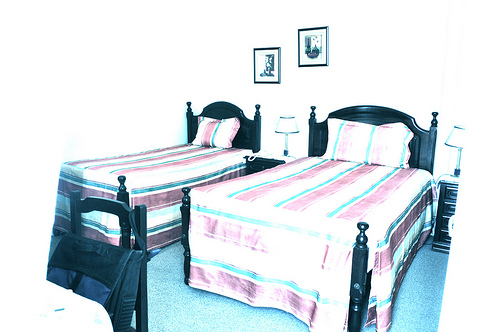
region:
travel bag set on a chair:
[60, 185, 155, 297]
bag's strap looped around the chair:
[122, 200, 147, 260]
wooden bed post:
[341, 215, 373, 317]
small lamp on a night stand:
[271, 106, 293, 148]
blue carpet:
[160, 300, 220, 327]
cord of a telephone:
[245, 150, 252, 160]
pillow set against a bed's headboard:
[321, 110, 411, 166]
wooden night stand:
[430, 175, 455, 250]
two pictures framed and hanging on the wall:
[246, 11, 331, 96]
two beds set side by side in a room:
[95, 51, 422, 316]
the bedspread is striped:
[264, 166, 390, 286]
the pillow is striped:
[327, 115, 426, 169]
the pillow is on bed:
[313, 120, 407, 217]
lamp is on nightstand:
[263, 100, 300, 162]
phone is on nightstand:
[249, 143, 275, 170]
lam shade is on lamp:
[273, 114, 298, 161]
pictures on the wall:
[248, 32, 345, 89]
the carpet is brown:
[153, 273, 278, 330]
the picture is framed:
[247, 30, 337, 94]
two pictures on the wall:
[245, 32, 354, 89]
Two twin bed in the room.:
[122, 118, 415, 293]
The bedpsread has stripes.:
[263, 153, 400, 231]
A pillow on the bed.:
[331, 120, 404, 175]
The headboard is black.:
[299, 99, 434, 173]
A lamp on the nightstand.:
[266, 105, 306, 157]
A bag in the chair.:
[54, 227, 139, 313]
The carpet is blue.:
[165, 263, 229, 322]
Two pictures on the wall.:
[242, 43, 337, 86]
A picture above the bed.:
[236, 49, 282, 92]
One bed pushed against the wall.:
[84, 100, 256, 171]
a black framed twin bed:
[177, 103, 439, 323]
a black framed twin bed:
[50, 99, 261, 273]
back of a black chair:
[65, 188, 150, 330]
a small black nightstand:
[433, 175, 458, 260]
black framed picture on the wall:
[297, 25, 330, 69]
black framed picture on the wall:
[252, 47, 279, 84]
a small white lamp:
[274, 115, 299, 157]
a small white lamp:
[444, 124, 465, 182]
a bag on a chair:
[47, 228, 143, 329]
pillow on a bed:
[192, 114, 239, 149]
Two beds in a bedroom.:
[60, 78, 440, 328]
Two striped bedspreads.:
[56, 137, 436, 327]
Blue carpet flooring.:
[50, 233, 445, 328]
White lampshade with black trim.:
[270, 110, 300, 136]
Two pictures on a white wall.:
[250, 21, 330, 83]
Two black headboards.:
[177, 97, 437, 172]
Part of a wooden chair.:
[65, 185, 150, 327]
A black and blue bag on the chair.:
[45, 227, 141, 327]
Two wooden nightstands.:
[241, 155, 458, 256]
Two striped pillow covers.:
[185, 115, 414, 168]